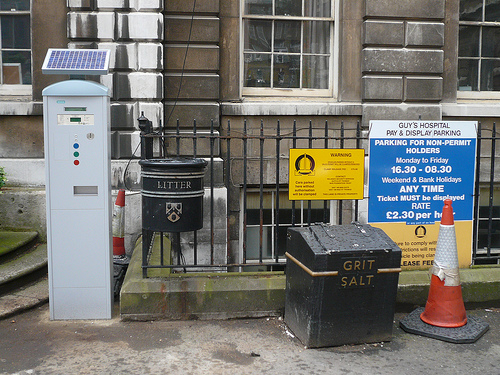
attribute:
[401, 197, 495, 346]
safety cone — orange, white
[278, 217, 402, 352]
salt box — black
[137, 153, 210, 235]
litter bin — black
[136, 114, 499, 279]
fence — wrought iron, black iron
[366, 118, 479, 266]
sign — blue, white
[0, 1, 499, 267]
building — brick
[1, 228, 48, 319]
steps — concrete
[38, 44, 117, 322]
ticket meter — off-white, tall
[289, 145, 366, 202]
sign — yellow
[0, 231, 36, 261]
step — moss-covered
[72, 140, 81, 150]
button — blue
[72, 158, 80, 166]
button — red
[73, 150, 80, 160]
button — green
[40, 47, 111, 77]
solar power panel — small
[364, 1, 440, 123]
brick — grey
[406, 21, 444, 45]
brick — grey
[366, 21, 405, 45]
brick — grey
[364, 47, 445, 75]
brick — grey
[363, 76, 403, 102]
brick — grey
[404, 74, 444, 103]
brick — grey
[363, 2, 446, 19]
brick — grey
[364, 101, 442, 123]
brick — grey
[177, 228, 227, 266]
brick — grey